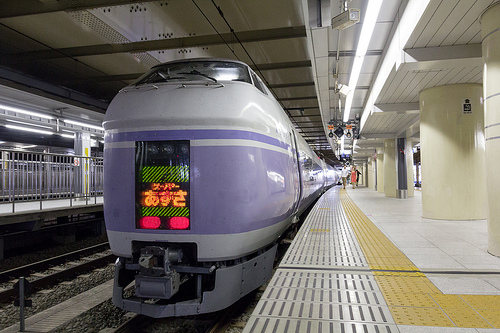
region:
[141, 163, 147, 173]
green light line on train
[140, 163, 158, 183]
green light line on train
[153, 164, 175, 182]
green light line on train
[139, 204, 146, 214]
green light line on train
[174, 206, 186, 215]
green light line on train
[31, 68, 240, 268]
this is a train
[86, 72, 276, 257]
this is a metro train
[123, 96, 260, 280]
the train is white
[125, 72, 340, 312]
the train is pastel colors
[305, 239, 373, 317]
the platform is metal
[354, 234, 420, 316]
the line is yellow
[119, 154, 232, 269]
the signs are lit up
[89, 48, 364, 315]
blue and grey subway train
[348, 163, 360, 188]
woman in pink dress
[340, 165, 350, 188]
person in white shirt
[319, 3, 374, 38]
security camera hanging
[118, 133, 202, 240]
light up display on subway train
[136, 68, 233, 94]
subway train windshield wipers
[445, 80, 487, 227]
column with sign on it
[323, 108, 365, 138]
orange and black signs hanging in the background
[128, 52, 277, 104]
front window of subway train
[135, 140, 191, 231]
illuminated display mounted on train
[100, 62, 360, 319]
train stopped in a train station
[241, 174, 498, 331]
platform to the right of train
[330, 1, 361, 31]
security camera hanging above platform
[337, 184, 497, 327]
yellow stripe on surface of platform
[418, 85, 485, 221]
large cylindrical support to the right of train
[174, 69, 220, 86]
windshield wiper on top of windshield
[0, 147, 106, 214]
metal railing to the left of train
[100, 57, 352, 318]
A train with purple stripes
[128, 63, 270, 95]
The windshield of a train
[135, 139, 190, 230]
A display on a train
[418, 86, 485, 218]
White pillar is wide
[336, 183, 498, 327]
A yellow stripe on platform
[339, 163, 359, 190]
Two people in background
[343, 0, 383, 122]
A long string of lights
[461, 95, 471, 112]
A sign on a pillar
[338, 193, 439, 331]
yellow tiles on floor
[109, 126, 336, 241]
purple stripe on train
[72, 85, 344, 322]
this is a passenger train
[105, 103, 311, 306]
the train is purple and white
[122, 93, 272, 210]
the train is metal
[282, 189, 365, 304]
the platform is metal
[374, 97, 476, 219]
the pillar is large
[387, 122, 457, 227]
the pillar is stone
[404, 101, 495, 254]
the pillar is round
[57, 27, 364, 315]
The train is blue and white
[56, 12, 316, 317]
The train has an electronic sign on the front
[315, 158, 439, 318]
The platform has a yellow line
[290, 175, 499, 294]
The platform floor is white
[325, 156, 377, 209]
A person in a red dress is on the platform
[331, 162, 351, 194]
A person in a white shirt is on the platform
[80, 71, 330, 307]
The train has a grey stripe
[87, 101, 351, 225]
The train has a blue stripe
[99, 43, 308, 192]
The train has a windshield